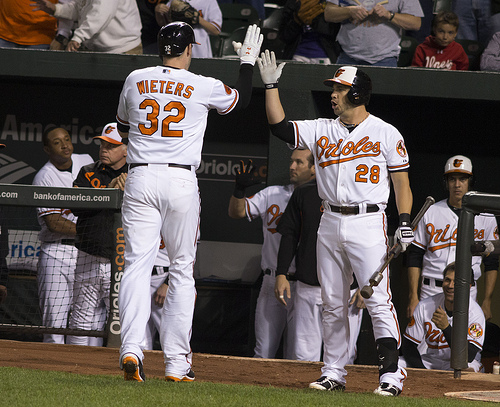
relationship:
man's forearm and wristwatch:
[397, 12, 419, 31] [386, 7, 396, 22]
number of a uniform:
[137, 96, 187, 138] [113, 63, 242, 373]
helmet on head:
[158, 20, 200, 46] [141, 12, 198, 68]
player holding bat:
[251, 46, 417, 403] [359, 195, 433, 299]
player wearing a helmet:
[416, 160, 497, 310] [435, 141, 489, 189]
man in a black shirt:
[271, 170, 321, 368] [274, 183, 321, 285]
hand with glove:
[232, 22, 261, 66] [234, 20, 263, 67]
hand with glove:
[256, 46, 288, 86] [254, 50, 284, 84]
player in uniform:
[116, 18, 268, 388] [113, 63, 242, 373]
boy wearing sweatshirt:
[408, 34, 477, 74] [408, 36, 479, 76]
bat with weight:
[380, 193, 443, 270] [359, 266, 384, 304]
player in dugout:
[401, 263, 484, 367] [11, 262, 483, 363]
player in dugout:
[405, 154, 499, 321] [11, 262, 483, 363]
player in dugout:
[34, 127, 100, 331] [11, 262, 483, 363]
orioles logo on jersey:
[311, 131, 382, 163] [286, 114, 410, 205]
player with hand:
[116, 18, 268, 388] [226, 16, 268, 69]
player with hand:
[251, 46, 417, 403] [257, 50, 285, 85]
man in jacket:
[64, 122, 128, 348] [68, 160, 126, 260]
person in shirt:
[327, 1, 425, 71] [331, 4, 426, 64]